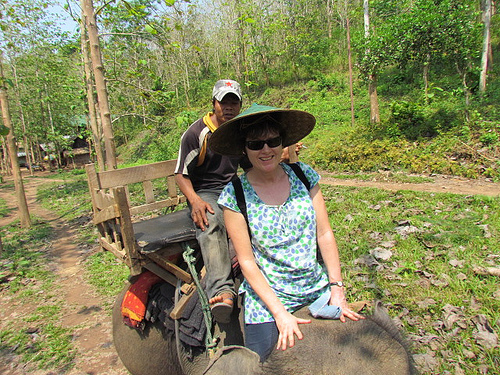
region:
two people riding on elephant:
[104, 72, 420, 365]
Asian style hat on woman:
[202, 90, 325, 159]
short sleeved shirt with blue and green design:
[214, 147, 333, 335]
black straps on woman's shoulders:
[224, 144, 316, 230]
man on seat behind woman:
[177, 72, 252, 330]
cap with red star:
[210, 66, 255, 111]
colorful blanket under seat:
[111, 266, 166, 331]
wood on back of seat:
[117, 147, 177, 204]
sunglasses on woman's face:
[243, 132, 286, 154]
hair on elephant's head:
[337, 323, 399, 362]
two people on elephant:
[172, 83, 356, 337]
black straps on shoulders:
[232, 143, 317, 227]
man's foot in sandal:
[208, 290, 235, 325]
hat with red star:
[212, 79, 242, 104]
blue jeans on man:
[199, 191, 223, 305]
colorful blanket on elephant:
[116, 273, 162, 333]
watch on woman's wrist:
[327, 279, 347, 291]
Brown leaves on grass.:
[364, 196, 472, 313]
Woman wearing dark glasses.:
[206, 96, 342, 186]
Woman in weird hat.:
[200, 91, 330, 161]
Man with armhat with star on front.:
[202, 65, 277, 115]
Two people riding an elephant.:
[93, 72, 434, 367]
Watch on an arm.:
[311, 267, 353, 301]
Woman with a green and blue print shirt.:
[208, 111, 360, 335]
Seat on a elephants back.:
[77, 107, 256, 372]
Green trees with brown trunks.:
[2, 40, 114, 206]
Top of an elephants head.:
[166, 320, 443, 373]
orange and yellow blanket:
[104, 275, 155, 344]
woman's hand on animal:
[268, 312, 320, 362]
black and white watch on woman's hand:
[323, 276, 373, 302]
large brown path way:
[333, 165, 488, 207]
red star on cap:
[205, 76, 237, 89]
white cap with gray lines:
[191, 75, 247, 106]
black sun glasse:
[239, 134, 302, 157]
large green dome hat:
[205, 102, 368, 154]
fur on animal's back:
[319, 312, 424, 368]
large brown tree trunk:
[60, 9, 135, 235]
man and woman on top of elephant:
[85, 35, 420, 360]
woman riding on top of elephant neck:
[200, 95, 380, 345]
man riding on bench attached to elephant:
[170, 35, 250, 315]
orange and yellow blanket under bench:
[101, 266, 176, 331]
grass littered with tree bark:
[342, 181, 483, 336]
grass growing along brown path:
[15, 146, 105, 362]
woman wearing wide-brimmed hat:
[185, 86, 341, 171]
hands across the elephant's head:
[250, 276, 395, 347]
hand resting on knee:
[165, 162, 222, 254]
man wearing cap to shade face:
[185, 65, 255, 121]